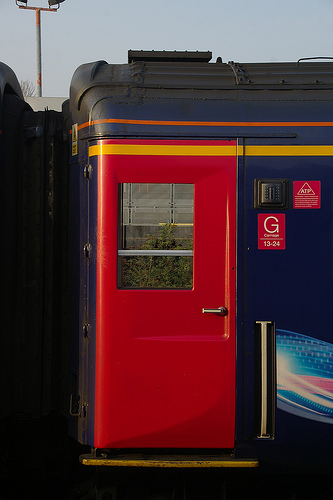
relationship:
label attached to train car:
[290, 180, 320, 209] [67, 48, 333, 472]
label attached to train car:
[254, 212, 287, 252] [67, 48, 333, 472]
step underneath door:
[79, 452, 259, 467] [88, 124, 272, 498]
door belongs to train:
[91, 138, 238, 450] [0, 50, 333, 498]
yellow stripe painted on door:
[110, 128, 230, 177] [91, 138, 238, 450]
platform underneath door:
[81, 451, 259, 471] [91, 138, 238, 450]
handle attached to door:
[198, 302, 220, 317] [91, 138, 238, 450]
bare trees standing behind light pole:
[20, 79, 37, 96] [13, 0, 65, 96]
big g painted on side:
[257, 215, 282, 232] [73, 97, 329, 424]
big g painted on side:
[264, 215, 280, 233] [65, 100, 321, 452]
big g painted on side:
[264, 215, 280, 233] [59, 132, 97, 482]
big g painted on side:
[264, 215, 280, 233] [76, 50, 327, 499]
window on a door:
[120, 182, 193, 290] [91, 138, 238, 450]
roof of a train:
[72, 56, 322, 138] [72, 85, 330, 423]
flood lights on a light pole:
[11, 0, 66, 10] [13, 0, 65, 96]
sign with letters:
[254, 213, 288, 251] [257, 211, 283, 250]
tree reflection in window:
[128, 225, 191, 284] [119, 182, 202, 287]